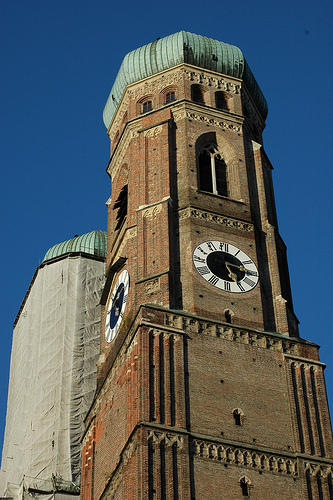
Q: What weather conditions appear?
A: It is clear.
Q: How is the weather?
A: It is clear.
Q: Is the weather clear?
A: Yes, it is clear.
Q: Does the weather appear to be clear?
A: Yes, it is clear.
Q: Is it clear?
A: Yes, it is clear.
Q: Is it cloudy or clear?
A: It is clear.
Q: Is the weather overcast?
A: No, it is clear.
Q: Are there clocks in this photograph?
A: Yes, there is a clock.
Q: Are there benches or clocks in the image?
A: Yes, there is a clock.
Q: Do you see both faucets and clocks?
A: No, there is a clock but no faucets.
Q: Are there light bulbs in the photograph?
A: No, there are no light bulbs.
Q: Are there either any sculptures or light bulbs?
A: No, there are no light bulbs or sculptures.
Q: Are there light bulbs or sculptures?
A: No, there are no light bulbs or sculptures.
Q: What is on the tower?
A: The clock is on the tower.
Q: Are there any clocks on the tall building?
A: Yes, there is a clock on the tower.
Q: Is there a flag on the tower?
A: No, there is a clock on the tower.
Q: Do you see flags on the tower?
A: No, there is a clock on the tower.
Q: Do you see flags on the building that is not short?
A: No, there is a clock on the tower.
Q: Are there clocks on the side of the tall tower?
A: Yes, there is a clock on the side of the tower.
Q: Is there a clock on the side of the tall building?
A: Yes, there is a clock on the side of the tower.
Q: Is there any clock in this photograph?
A: Yes, there is a clock.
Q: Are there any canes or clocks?
A: Yes, there is a clock.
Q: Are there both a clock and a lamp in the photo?
A: No, there is a clock but no lamps.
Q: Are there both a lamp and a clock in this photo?
A: No, there is a clock but no lamps.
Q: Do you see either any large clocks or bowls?
A: Yes, there is a large clock.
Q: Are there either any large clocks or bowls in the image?
A: Yes, there is a large clock.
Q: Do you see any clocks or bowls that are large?
A: Yes, the clock is large.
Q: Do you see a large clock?
A: Yes, there is a large clock.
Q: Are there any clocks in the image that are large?
A: Yes, there is a clock that is large.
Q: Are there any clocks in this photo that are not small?
A: Yes, there is a large clock.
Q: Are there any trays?
A: No, there are no trays.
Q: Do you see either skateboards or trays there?
A: No, there are no trays or skateboards.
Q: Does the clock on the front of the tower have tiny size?
A: No, the clock is large.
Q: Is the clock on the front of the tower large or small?
A: The clock is large.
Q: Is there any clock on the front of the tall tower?
A: Yes, there is a clock on the front of the tower.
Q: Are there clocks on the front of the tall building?
A: Yes, there is a clock on the front of the tower.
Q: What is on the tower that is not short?
A: The clock is on the tower.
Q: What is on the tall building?
A: The clock is on the tower.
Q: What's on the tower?
A: The clock is on the tower.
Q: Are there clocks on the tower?
A: Yes, there is a clock on the tower.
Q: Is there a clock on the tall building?
A: Yes, there is a clock on the tower.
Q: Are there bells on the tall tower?
A: No, there is a clock on the tower.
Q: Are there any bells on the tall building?
A: No, there is a clock on the tower.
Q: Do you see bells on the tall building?
A: No, there is a clock on the tower.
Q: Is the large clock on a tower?
A: Yes, the clock is on a tower.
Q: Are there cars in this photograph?
A: No, there are no cars.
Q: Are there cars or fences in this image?
A: No, there are no cars or fences.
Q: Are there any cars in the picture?
A: No, there are no cars.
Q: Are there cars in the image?
A: No, there are no cars.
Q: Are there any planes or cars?
A: No, there are no cars or planes.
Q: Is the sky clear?
A: Yes, the sky is clear.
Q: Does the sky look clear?
A: Yes, the sky is clear.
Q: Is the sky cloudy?
A: No, the sky is clear.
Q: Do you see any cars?
A: No, there are no cars.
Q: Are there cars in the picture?
A: No, there are no cars.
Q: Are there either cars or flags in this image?
A: No, there are no cars or flags.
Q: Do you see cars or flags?
A: No, there are no cars or flags.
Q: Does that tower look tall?
A: Yes, the tower is tall.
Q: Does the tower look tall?
A: Yes, the tower is tall.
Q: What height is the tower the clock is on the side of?
A: The tower is tall.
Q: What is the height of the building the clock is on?
A: The tower is tall.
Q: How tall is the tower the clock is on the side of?
A: The tower is tall.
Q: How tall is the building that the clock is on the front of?
A: The tower is tall.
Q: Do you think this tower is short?
A: No, the tower is tall.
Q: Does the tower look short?
A: No, the tower is tall.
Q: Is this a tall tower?
A: Yes, this is a tall tower.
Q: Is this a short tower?
A: No, this is a tall tower.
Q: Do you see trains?
A: No, there are no trains.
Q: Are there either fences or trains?
A: No, there are no trains or fences.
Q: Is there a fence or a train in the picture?
A: No, there are no trains or fences.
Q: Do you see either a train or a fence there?
A: No, there are no trains or fences.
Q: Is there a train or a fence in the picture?
A: No, there are no trains or fences.